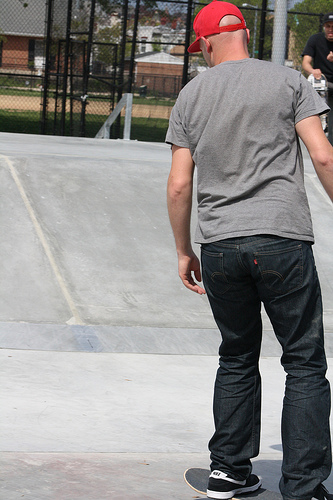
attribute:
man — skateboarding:
[168, 0, 332, 499]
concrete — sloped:
[0, 133, 330, 498]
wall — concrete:
[0, 131, 332, 354]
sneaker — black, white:
[207, 470, 262, 499]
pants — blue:
[201, 234, 332, 499]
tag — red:
[253, 258, 260, 264]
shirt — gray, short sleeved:
[164, 59, 331, 245]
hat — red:
[187, 0, 246, 53]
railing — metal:
[94, 91, 134, 139]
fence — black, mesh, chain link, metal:
[3, 2, 332, 142]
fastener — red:
[218, 24, 247, 32]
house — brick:
[1, 1, 92, 84]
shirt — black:
[302, 33, 333, 81]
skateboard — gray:
[184, 467, 285, 499]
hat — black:
[322, 15, 332, 25]